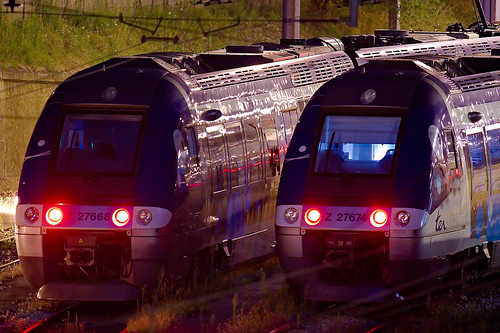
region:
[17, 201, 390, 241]
train lights are on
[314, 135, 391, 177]
lights on inside train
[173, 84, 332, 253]
reflection on side of train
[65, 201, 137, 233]
black numbers on train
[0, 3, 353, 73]
wires above the train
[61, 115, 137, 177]
dark inside the train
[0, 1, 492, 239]
grass on side of track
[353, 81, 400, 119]
light above the window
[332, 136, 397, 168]
blue lights inside train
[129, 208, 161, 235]
light is turned off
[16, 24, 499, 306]
a couple of trains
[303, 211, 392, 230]
lights on a train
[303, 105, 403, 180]
a window on a train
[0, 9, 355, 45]
a electric wire over train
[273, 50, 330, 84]
vent on the side of the train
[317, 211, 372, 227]
a number on the front of the train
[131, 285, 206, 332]
green grass along the track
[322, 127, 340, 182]
a windshield wiper on a train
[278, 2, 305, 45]
a gray metal pole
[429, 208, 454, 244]
writing on the side of train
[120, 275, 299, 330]
overgrown weeds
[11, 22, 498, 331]
two electric trains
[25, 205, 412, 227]
lights for signaling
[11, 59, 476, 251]
front of train for conductor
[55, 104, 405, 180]
windows for conductor to see from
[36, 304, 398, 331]
railroad track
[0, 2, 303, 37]
electrical poles and wires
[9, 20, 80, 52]
overgrown grass on hillside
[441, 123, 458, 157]
side window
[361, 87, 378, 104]
main train light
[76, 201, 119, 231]
Numbers on the train.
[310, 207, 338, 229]
Z on the train.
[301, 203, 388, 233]
Lights on the train.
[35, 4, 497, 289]
There are two trains.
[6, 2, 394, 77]
Wires above the trains.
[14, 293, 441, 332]
The trains are on tracks.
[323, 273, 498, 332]
Gravel around the tracks.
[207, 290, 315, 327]
Grass by the tracks.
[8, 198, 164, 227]
Two lights are not on.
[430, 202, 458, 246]
Ter on the train.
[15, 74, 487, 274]
two trains side by side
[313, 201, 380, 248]
number of the train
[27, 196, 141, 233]
lights on train on right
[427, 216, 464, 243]
lettering on side of train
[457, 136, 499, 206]
windows on side of train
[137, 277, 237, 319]
high grass on tracks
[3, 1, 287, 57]
electrical wires for the train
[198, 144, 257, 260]
blue coloring on the side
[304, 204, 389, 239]
two bright lights on the front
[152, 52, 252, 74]
top is opened on the train